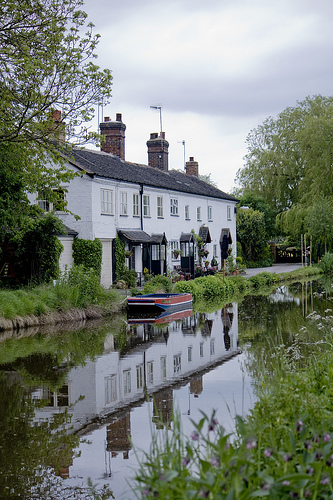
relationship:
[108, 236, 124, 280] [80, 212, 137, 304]
ivy growing up wall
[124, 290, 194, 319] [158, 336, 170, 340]
boat on water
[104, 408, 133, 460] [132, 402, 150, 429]
chimney reflection in water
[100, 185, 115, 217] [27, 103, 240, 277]
window on building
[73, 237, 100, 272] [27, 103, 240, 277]
ivy on building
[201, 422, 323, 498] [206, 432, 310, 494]
flowers on plant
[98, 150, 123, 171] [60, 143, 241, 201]
tiles on roof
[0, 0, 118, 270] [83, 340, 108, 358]
tree hanging over water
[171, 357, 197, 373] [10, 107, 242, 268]
water in front house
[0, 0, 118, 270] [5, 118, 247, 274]
tree beside house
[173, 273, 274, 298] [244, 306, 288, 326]
bushes along river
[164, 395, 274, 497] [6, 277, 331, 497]
flowers at water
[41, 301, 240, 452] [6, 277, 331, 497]
building reflected in water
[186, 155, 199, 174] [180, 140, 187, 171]
chimney with antenna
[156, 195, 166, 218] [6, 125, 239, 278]
window on building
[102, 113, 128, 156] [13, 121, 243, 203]
chimney on roof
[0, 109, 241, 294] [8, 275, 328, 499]
building along river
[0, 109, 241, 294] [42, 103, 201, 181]
building has chimneys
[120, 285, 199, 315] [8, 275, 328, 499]
boat on river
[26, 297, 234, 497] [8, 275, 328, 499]
reflection cast on river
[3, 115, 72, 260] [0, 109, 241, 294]
tree growing next to building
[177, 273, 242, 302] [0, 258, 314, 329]
bushes growing next to river bank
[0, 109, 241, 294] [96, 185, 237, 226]
building has windows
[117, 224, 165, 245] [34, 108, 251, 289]
overhang on building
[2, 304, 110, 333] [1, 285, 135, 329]
grass on bank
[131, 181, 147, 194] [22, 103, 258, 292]
gutter on side of building